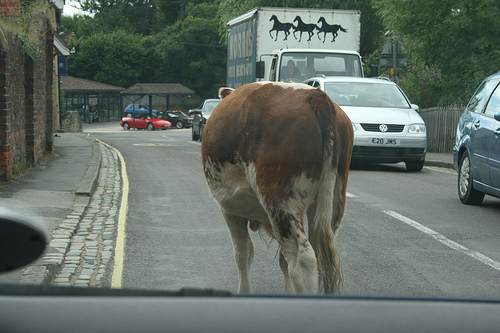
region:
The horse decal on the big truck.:
[262, 13, 350, 43]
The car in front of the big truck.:
[314, 70, 436, 160]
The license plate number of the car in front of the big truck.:
[367, 135, 403, 147]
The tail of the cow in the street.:
[314, 91, 350, 292]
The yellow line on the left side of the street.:
[89, 134, 146, 291]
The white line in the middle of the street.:
[362, 188, 497, 295]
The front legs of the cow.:
[221, 212, 296, 294]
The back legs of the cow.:
[274, 173, 343, 291]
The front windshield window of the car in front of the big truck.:
[327, 80, 405, 105]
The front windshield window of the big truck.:
[279, 52, 365, 76]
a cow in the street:
[201, 81, 354, 293]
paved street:
[92, 130, 497, 296]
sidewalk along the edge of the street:
[3, 129, 100, 291]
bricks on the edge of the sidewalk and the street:
[38, 128, 120, 288]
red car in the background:
[120, 111, 170, 130]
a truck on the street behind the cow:
[225, 7, 365, 88]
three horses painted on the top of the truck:
[267, 12, 347, 43]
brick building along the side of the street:
[0, 0, 62, 189]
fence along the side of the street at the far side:
[416, 105, 472, 150]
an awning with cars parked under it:
[121, 80, 193, 126]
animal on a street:
[190, 71, 367, 313]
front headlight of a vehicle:
[403, 118, 428, 139]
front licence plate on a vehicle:
[366, 132, 406, 151]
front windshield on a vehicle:
[318, 74, 417, 112]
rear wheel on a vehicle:
[449, 140, 491, 208]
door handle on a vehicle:
[471, 117, 484, 129]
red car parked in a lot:
[118, 108, 175, 135]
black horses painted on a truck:
[264, 10, 353, 46]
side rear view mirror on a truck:
[249, 50, 281, 83]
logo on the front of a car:
[375, 119, 393, 135]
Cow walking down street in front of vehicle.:
[188, 78, 386, 293]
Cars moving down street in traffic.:
[310, 62, 498, 213]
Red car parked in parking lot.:
[111, 111, 171, 134]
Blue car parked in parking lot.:
[118, 99, 161, 118]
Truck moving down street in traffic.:
[216, 2, 373, 94]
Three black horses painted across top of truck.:
[265, 10, 350, 42]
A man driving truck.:
[280, 57, 307, 84]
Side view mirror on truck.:
[245, 46, 278, 81]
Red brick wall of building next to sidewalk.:
[5, 35, 60, 177]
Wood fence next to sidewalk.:
[423, 103, 466, 155]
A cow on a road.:
[199, 78, 379, 295]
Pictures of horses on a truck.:
[265, 12, 351, 44]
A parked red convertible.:
[115, 106, 175, 141]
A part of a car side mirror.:
[1, 181, 72, 288]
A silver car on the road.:
[301, 68, 446, 183]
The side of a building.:
[1, 1, 66, 194]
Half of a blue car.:
[441, 58, 498, 217]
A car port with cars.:
[119, 75, 203, 140]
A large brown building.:
[56, 74, 130, 129]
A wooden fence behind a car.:
[391, 94, 493, 173]